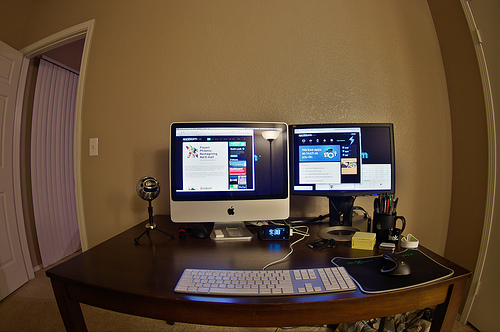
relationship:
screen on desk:
[166, 120, 289, 221] [43, 204, 478, 329]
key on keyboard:
[296, 285, 303, 291] [173, 262, 357, 297]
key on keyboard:
[316, 285, 323, 293] [173, 262, 357, 297]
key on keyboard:
[292, 272, 302, 279] [173, 262, 357, 297]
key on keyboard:
[303, 282, 313, 287] [173, 262, 357, 297]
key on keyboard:
[271, 281, 292, 293] [173, 262, 357, 297]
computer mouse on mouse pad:
[379, 252, 414, 278] [322, 230, 459, 302]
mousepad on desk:
[330, 245, 455, 292] [43, 204, 478, 329]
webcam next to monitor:
[112, 142, 164, 216] [162, 116, 292, 242]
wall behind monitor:
[4, 2, 451, 255] [162, 116, 292, 242]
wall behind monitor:
[4, 2, 451, 255] [285, 122, 396, 245]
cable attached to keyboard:
[259, 222, 310, 271] [172, 265, 357, 296]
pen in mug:
[374, 192, 398, 216] [369, 194, 406, 236]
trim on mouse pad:
[330, 245, 456, 296] [322, 242, 457, 295]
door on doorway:
[27, 57, 79, 272] [10, 14, 95, 270]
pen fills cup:
[372, 187, 402, 208] [350, 211, 425, 270]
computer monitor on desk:
[165, 115, 293, 244] [43, 204, 478, 329]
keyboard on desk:
[172, 265, 357, 296] [43, 204, 478, 329]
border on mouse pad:
[329, 247, 457, 295] [323, 247, 459, 328]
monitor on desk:
[293, 120, 395, 194] [43, 204, 478, 329]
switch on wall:
[84, 130, 104, 158] [88, 9, 453, 308]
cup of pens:
[373, 212, 404, 236] [370, 191, 400, 213]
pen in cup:
[374, 192, 398, 216] [372, 211, 406, 242]